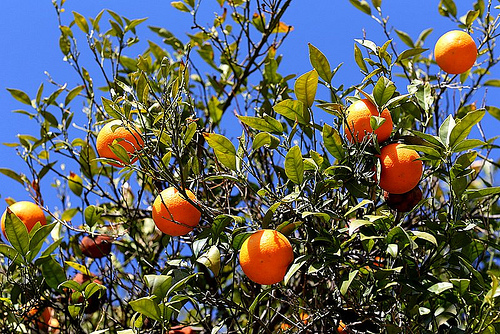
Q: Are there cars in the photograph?
A: No, there are no cars.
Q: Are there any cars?
A: No, there are no cars.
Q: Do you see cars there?
A: No, there are no cars.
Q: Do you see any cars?
A: No, there are no cars.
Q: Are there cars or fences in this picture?
A: No, there are no cars or fences.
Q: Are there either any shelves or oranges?
A: Yes, there are oranges.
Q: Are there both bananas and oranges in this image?
A: No, there are oranges but no bananas.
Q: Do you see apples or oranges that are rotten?
A: Yes, the oranges are rotten.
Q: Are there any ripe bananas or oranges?
A: Yes, there are ripe oranges.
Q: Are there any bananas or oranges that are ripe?
A: Yes, the oranges are ripe.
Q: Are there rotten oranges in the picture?
A: Yes, there are rotten oranges.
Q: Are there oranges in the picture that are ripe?
A: Yes, there are oranges that are ripe.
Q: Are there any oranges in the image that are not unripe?
A: Yes, there are ripe oranges.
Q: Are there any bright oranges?
A: Yes, there are bright oranges.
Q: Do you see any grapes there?
A: No, there are no grapes.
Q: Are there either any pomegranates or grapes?
A: No, there are no grapes or pomegranates.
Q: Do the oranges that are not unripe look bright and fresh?
A: No, the oranges are bright but rotten.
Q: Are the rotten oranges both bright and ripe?
A: Yes, the oranges are bright and ripe.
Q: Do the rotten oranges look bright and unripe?
A: No, the oranges are bright but ripe.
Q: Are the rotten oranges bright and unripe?
A: No, the oranges are bright but ripe.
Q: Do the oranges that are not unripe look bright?
A: Yes, the oranges are bright.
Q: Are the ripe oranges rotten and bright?
A: Yes, the oranges are rotten and bright.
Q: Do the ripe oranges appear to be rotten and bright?
A: Yes, the oranges are rotten and bright.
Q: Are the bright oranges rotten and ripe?
A: Yes, the oranges are rotten and ripe.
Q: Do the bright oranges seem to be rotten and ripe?
A: Yes, the oranges are rotten and ripe.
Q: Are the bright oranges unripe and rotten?
A: No, the oranges are rotten but ripe.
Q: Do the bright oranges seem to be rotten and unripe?
A: No, the oranges are rotten but ripe.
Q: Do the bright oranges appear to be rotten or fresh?
A: The oranges are rotten.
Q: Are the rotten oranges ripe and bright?
A: Yes, the oranges are ripe and bright.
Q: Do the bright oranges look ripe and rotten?
A: Yes, the oranges are ripe and rotten.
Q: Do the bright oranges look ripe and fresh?
A: No, the oranges are ripe but rotten.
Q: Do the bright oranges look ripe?
A: Yes, the oranges are ripe.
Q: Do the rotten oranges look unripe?
A: No, the oranges are ripe.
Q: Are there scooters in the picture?
A: No, there are no scooters.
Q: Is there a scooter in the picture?
A: No, there are no scooters.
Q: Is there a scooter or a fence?
A: No, there are no scooters or fences.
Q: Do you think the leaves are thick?
A: Yes, the leaves are thick.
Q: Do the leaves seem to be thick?
A: Yes, the leaves are thick.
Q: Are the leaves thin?
A: No, the leaves are thick.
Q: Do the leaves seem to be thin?
A: No, the leaves are thick.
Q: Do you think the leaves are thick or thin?
A: The leaves are thick.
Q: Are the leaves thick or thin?
A: The leaves are thick.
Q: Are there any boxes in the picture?
A: No, there are no boxes.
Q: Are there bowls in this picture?
A: No, there are no bowls.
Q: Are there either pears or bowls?
A: No, there are no bowls or pears.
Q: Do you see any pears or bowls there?
A: No, there are no bowls or pears.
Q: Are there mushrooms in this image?
A: No, there are no mushrooms.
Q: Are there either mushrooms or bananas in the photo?
A: No, there are no mushrooms or bananas.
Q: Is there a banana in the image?
A: No, there are no bananas.